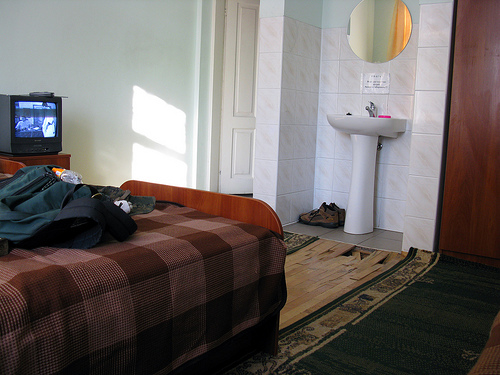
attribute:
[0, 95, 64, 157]
tv — turned on, old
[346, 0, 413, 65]
mirror — small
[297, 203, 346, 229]
shoes — brown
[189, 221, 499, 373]
floor — broken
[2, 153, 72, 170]
table — small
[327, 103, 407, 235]
sink — white, standing, tall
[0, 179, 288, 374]
bed — small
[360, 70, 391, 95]
sign — white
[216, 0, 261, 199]
door — white, wooden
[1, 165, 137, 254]
backpack — green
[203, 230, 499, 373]
rug — green